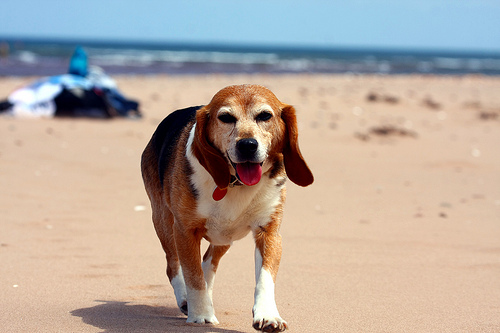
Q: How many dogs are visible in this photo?
A: One.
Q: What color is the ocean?
A: Blue.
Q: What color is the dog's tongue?
A: Pink.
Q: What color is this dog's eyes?
A: Black.